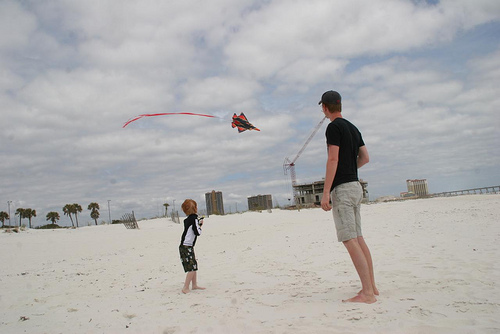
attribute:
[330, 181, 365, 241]
shorts — tan, grey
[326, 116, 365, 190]
shirt — black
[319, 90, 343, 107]
hat — black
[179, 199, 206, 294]
boy — young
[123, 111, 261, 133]
kite — black, orange, red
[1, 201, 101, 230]
palm trees — green, far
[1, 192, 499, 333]
sand — tan, soft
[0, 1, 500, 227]
sky — cloudy, black, red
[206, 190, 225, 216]
building — tall, far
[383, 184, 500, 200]
pier — far